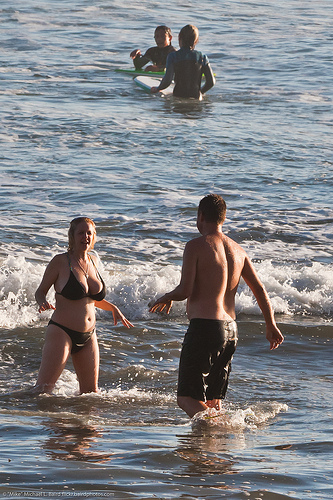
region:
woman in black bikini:
[20, 207, 129, 409]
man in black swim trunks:
[145, 184, 290, 438]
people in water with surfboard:
[113, 16, 226, 123]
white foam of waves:
[110, 261, 176, 293]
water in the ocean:
[12, 112, 322, 192]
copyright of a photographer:
[2, 486, 122, 498]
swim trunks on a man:
[171, 316, 250, 410]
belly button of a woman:
[82, 313, 94, 326]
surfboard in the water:
[133, 74, 156, 85]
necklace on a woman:
[76, 260, 95, 284]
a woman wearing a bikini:
[33, 216, 134, 396]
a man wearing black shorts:
[152, 192, 286, 419]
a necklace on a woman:
[70, 249, 90, 277]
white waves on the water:
[1, 243, 331, 324]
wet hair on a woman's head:
[67, 217, 96, 248]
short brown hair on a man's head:
[199, 194, 226, 222]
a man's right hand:
[265, 326, 283, 351]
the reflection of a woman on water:
[33, 403, 111, 463]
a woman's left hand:
[111, 305, 133, 330]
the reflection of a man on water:
[176, 429, 252, 476]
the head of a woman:
[66, 213, 99, 256]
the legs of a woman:
[33, 324, 106, 394]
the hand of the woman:
[31, 293, 60, 318]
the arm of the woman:
[32, 254, 60, 298]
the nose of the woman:
[81, 230, 88, 240]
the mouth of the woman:
[79, 237, 90, 245]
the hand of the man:
[147, 286, 176, 316]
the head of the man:
[194, 190, 226, 233]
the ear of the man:
[196, 208, 206, 222]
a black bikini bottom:
[45, 316, 99, 355]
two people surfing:
[123, 22, 232, 107]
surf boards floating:
[115, 64, 185, 91]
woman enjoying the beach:
[15, 220, 127, 401]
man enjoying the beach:
[143, 195, 287, 439]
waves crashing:
[2, 252, 327, 318]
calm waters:
[27, 55, 321, 191]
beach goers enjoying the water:
[26, 207, 331, 336]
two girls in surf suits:
[129, 45, 248, 109]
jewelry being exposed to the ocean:
[69, 258, 92, 280]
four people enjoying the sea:
[11, 7, 321, 385]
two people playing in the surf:
[27, 185, 286, 464]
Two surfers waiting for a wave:
[113, 8, 223, 114]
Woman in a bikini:
[19, 190, 133, 426]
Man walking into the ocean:
[143, 185, 283, 431]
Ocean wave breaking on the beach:
[262, 251, 324, 324]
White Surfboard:
[127, 64, 168, 93]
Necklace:
[75, 259, 88, 276]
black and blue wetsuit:
[157, 48, 216, 96]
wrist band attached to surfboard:
[128, 44, 145, 61]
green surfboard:
[118, 56, 167, 77]